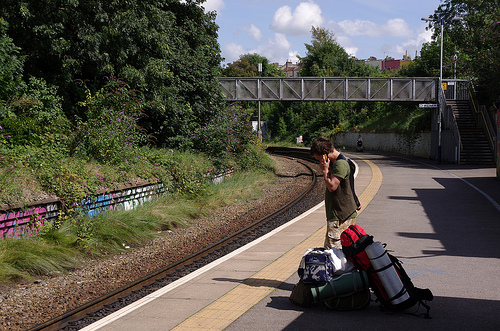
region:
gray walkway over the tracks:
[209, 72, 447, 103]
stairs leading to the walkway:
[432, 75, 499, 165]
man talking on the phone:
[308, 131, 362, 251]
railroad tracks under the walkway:
[16, 142, 328, 329]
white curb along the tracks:
[72, 153, 356, 329]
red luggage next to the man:
[336, 220, 400, 307]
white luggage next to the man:
[363, 237, 410, 312]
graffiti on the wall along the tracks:
[2, 164, 238, 241]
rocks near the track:
[2, 155, 302, 327]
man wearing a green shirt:
[318, 157, 361, 217]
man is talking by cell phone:
[288, 125, 381, 242]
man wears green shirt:
[302, 122, 367, 240]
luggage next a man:
[290, 125, 437, 318]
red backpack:
[332, 215, 375, 267]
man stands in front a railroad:
[96, 120, 442, 321]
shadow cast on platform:
[382, 145, 499, 265]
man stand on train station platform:
[264, 123, 436, 313]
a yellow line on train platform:
[179, 275, 308, 327]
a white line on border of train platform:
[138, 238, 224, 297]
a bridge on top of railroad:
[196, 60, 441, 111]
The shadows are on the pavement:
[209, 259, 331, 329]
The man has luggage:
[279, 232, 449, 305]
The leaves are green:
[48, 35, 233, 185]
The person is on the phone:
[299, 120, 356, 206]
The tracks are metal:
[95, 177, 205, 305]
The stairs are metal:
[424, 69, 498, 194]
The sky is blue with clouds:
[248, 30, 315, 70]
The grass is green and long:
[5, 155, 245, 284]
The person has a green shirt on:
[302, 158, 367, 224]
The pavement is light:
[379, 189, 451, 268]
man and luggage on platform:
[297, 131, 433, 310]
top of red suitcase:
[338, 223, 365, 249]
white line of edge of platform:
[84, 200, 327, 326]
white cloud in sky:
[269, 3, 324, 30]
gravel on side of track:
[5, 159, 298, 324]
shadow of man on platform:
[212, 276, 296, 291]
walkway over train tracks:
[214, 76, 439, 167]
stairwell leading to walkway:
[435, 78, 495, 163]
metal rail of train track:
[33, 156, 313, 328]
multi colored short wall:
[2, 172, 225, 244]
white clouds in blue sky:
[230, 6, 275, 48]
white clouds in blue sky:
[275, 10, 300, 40]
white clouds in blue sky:
[337, 11, 378, 51]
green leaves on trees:
[28, 7, 88, 67]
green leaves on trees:
[20, 72, 75, 118]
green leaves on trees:
[97, 26, 149, 97]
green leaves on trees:
[146, 27, 206, 80]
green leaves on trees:
[471, 20, 497, 60]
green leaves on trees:
[72, 115, 123, 141]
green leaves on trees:
[179, 116, 213, 156]